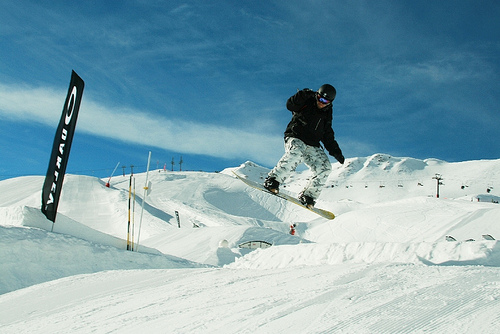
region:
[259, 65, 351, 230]
man wearing black ski helmet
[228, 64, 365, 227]
man in the air on a snowboard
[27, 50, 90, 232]
black flag with white letters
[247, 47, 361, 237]
man wearing gray and white pants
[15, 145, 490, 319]
ground covered in thick snow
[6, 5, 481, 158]
sky is blue and no clouds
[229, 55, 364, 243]
the man is snowboarding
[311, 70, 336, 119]
the helmet is black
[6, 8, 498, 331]
a scene during the day time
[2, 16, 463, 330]
a scene at the slopes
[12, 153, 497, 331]
snow on the ground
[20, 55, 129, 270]
a black banner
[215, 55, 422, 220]
a snowboarder in the air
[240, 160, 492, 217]
a ski lift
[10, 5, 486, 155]
s blue sky with clouds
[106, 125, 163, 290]
some poles sticking from the ground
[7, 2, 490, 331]
a scene outside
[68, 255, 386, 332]
tracks in the ground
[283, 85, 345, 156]
the jacket is black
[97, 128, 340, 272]
slopes made of snow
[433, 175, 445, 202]
This is a pole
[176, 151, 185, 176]
This is a pole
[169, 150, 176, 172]
This is a pole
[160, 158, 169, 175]
This is a pole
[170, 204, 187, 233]
This is a pole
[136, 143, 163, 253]
This is a pole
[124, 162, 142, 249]
This is a pole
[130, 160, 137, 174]
This is a pole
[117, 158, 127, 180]
This is a pole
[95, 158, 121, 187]
This is a pole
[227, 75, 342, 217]
Man jumping on snowboard.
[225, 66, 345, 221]
Snowboard performing a jump.